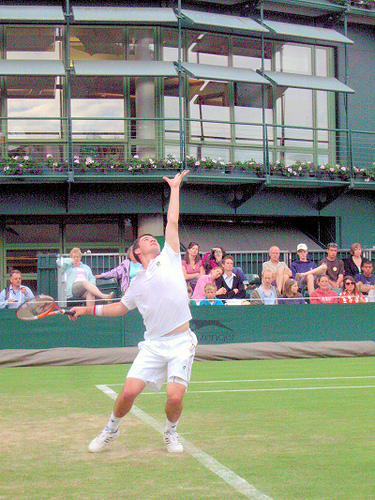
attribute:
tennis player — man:
[13, 164, 201, 474]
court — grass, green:
[1, 356, 373, 498]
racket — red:
[16, 293, 82, 328]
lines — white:
[188, 370, 374, 396]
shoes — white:
[80, 426, 188, 462]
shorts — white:
[123, 329, 194, 389]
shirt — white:
[120, 243, 197, 331]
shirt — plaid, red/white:
[342, 291, 367, 306]